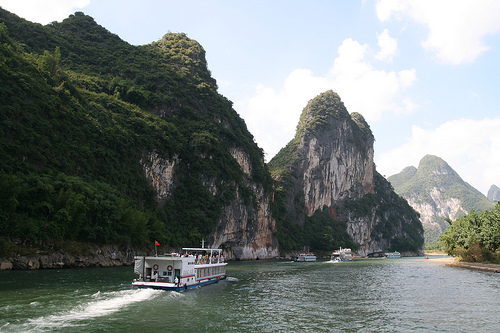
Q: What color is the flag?
A: Red.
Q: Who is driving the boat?
A: The captain.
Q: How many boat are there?
A: One.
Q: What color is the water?
A: Green.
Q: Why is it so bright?
A: Sunny.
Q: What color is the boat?
A: White.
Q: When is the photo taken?
A: Day time.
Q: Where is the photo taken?
A: Near water.